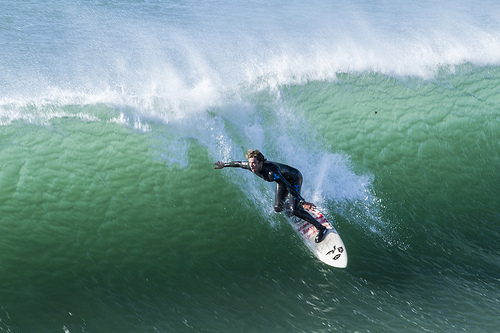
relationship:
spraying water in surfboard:
[104, 35, 374, 214] [281, 197, 349, 269]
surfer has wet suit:
[206, 134, 361, 265] [222, 159, 324, 231]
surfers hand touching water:
[206, 154, 237, 179] [1, 2, 499, 325]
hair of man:
[244, 147, 266, 162] [212, 144, 333, 244]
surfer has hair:
[206, 134, 351, 269] [244, 146, 268, 165]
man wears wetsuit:
[212, 144, 333, 244] [223, 160, 324, 235]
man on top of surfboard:
[212, 144, 333, 244] [207, 117, 377, 312]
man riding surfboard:
[212, 144, 333, 244] [272, 185, 349, 266]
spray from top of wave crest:
[38, 11, 458, 63] [0, 54, 494, 145]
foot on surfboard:
[298, 223, 333, 255] [281, 197, 349, 269]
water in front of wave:
[2, 267, 498, 330] [53, 60, 249, 180]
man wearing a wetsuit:
[212, 144, 333, 244] [230, 153, 335, 241]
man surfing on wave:
[212, 144, 333, 244] [2, 57, 499, 242]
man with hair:
[212, 144, 333, 244] [245, 149, 265, 161]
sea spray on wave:
[6, 14, 498, 107] [0, 64, 498, 291]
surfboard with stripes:
[281, 197, 349, 269] [291, 198, 337, 238]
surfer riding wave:
[206, 134, 361, 265] [239, 48, 485, 202]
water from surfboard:
[1, 51, 498, 326] [274, 187, 351, 269]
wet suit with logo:
[262, 154, 305, 215] [268, 168, 282, 183]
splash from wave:
[187, 42, 377, 102] [0, 64, 498, 291]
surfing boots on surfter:
[299, 211, 336, 251] [191, 129, 341, 246]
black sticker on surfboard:
[333, 251, 342, 261] [314, 234, 351, 270]